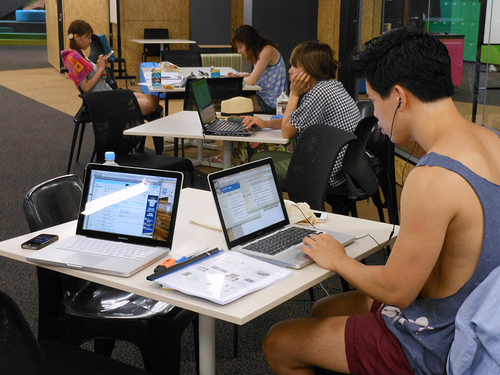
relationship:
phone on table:
[21, 232, 59, 251] [1, 186, 401, 374]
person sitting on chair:
[241, 40, 363, 188] [324, 116, 379, 217]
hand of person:
[302, 233, 348, 275] [261, 26, 499, 374]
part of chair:
[21, 171, 84, 234] [22, 172, 200, 374]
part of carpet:
[214, 244, 392, 374] [0, 71, 394, 374]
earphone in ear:
[397, 98, 404, 109] [393, 85, 408, 113]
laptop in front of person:
[207, 155, 356, 269] [261, 26, 499, 374]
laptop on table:
[26, 162, 185, 280] [1, 186, 401, 374]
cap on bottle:
[104, 151, 116, 161] [99, 151, 120, 166]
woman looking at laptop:
[241, 40, 363, 188] [189, 76, 256, 138]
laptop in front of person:
[189, 76, 256, 138] [241, 40, 363, 188]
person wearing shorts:
[261, 26, 499, 374] [290, 300, 344, 374]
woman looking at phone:
[60, 18, 160, 116] [103, 49, 115, 61]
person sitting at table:
[226, 23, 289, 113] [140, 66, 263, 95]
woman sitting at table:
[60, 18, 160, 116] [140, 66, 263, 95]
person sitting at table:
[241, 40, 363, 188] [124, 109, 291, 171]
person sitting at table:
[261, 26, 499, 374] [1, 186, 401, 374]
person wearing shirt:
[261, 26, 499, 374] [379, 124, 499, 373]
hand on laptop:
[302, 233, 348, 275] [207, 155, 356, 269]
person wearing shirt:
[226, 23, 289, 113] [257, 48, 287, 108]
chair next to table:
[79, 88, 197, 186] [124, 109, 291, 171]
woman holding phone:
[60, 18, 160, 116] [103, 49, 115, 61]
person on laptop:
[241, 40, 363, 188] [189, 76, 256, 138]